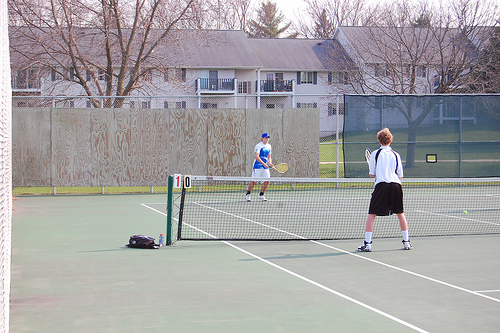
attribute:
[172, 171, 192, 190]
numbers — score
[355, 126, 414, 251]
man — playing tennis, plaig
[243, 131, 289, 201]
man — playing tennis, plaig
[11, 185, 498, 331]
court — green, white, fading, gree ad white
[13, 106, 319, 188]
boards — wood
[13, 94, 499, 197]
fence — high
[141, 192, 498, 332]
lines — white, boundaries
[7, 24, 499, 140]
building — distant, dwellig, large, white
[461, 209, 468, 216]
tennis ball — green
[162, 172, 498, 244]
net — black, white, boundaries, across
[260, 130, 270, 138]
hat — blue, protection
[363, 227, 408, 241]
socks — white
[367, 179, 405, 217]
shorts — black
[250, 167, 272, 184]
shorts — white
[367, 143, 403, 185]
shirt — black, white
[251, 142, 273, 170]
shirt — blue, white, blue ad white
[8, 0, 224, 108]
tree — bare, dormat, large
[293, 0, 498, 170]
tree — bare, dormat, large